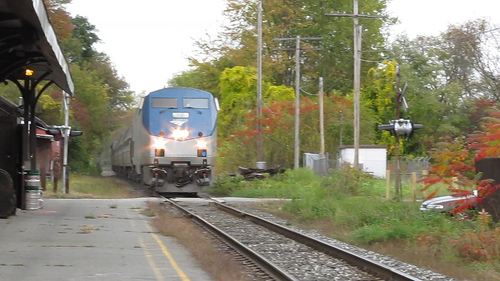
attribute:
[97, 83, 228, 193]
train — traveling, blue, gray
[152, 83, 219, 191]
front — blue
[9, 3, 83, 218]
station — here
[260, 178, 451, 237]
grass — growing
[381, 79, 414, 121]
sign — here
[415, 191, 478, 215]
car — parked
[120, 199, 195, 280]
lines — yellow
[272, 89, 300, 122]
leaves — red, yellow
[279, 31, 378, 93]
electric lines — here